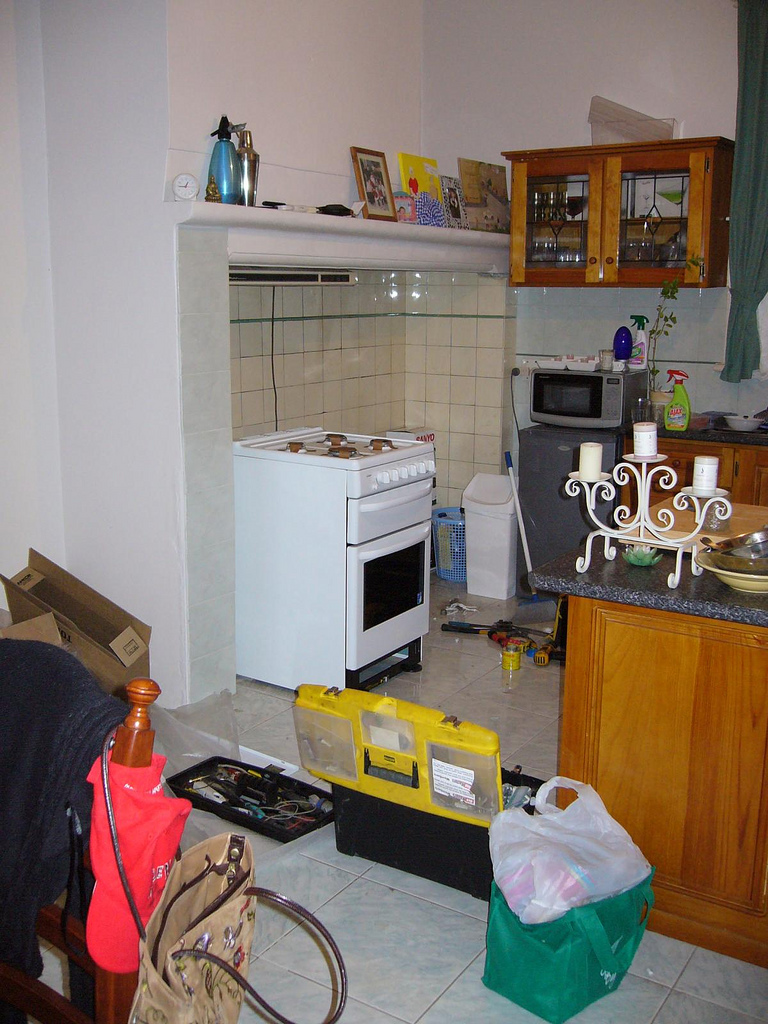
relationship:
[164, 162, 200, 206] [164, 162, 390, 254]
clock on shelf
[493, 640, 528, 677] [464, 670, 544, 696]
jar on ground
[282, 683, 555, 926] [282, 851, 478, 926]
tool box on ground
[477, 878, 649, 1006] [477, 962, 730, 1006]
bag on ground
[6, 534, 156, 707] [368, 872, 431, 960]
box on ground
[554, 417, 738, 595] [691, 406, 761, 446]
candle holder on counter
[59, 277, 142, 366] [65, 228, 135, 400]
tile on wall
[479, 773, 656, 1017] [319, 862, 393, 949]
bag on floor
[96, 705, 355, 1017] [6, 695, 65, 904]
bag hooked to chair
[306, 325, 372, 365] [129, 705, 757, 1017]
tile on floor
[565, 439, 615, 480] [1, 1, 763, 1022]
candle in kitchen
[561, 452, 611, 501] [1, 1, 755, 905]
candle in kitchen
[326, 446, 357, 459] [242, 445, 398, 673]
burner on stove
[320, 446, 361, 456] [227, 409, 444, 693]
burner on stove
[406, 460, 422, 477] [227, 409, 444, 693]
knob on stove